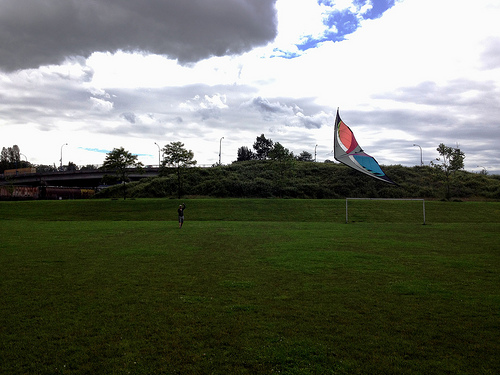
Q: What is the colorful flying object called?
A: Kite.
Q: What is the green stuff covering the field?
A: Grass.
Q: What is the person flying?
A: Kite.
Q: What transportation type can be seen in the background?
A: Train.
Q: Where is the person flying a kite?
A: Grassy field.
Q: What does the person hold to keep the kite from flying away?
A: String.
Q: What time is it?
A: Afternoon.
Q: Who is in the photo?
A: A person.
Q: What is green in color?
A: The grass.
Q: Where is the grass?
A: On the ground.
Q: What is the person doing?
A: Flying a kite.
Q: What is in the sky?
A: Clouds.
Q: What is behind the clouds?
A: Blue sky.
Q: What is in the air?
A: A kite.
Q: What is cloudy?
A: The sky.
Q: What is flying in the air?
A: Kite.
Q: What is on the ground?
A: Grass.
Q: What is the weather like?
A: Cloudy.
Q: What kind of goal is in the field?
A: Soccer.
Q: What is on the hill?
A: Tree.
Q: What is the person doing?
A: Flying a kite.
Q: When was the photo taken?
A: Daytime.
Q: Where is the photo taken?
A: Field.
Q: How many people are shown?
A: One.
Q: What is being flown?
A: Kites.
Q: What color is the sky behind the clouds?
A: Blue.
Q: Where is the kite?
A: Air.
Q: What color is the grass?
A: Green.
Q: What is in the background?
A: Trees.